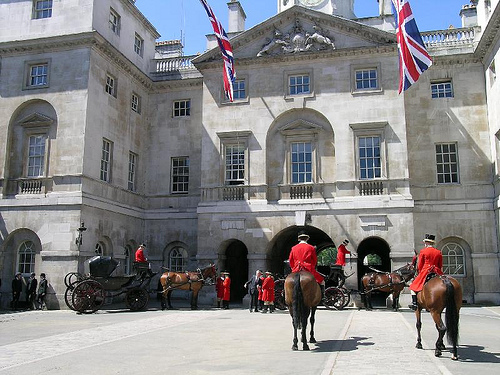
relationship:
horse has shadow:
[278, 264, 322, 354] [312, 333, 377, 359]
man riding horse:
[284, 233, 326, 309] [278, 264, 322, 354]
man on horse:
[284, 233, 326, 309] [278, 264, 322, 354]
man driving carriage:
[132, 239, 158, 277] [64, 254, 160, 313]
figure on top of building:
[253, 21, 341, 61] [3, 1, 500, 313]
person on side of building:
[35, 270, 51, 311] [3, 1, 500, 313]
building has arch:
[3, 1, 500, 313] [263, 227, 341, 269]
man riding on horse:
[284, 233, 326, 309] [278, 264, 322, 354]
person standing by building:
[35, 270, 51, 311] [3, 1, 500, 313]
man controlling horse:
[284, 233, 326, 309] [278, 264, 322, 354]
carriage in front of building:
[64, 254, 160, 313] [3, 1, 500, 313]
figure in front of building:
[253, 21, 341, 61] [3, 1, 500, 313]